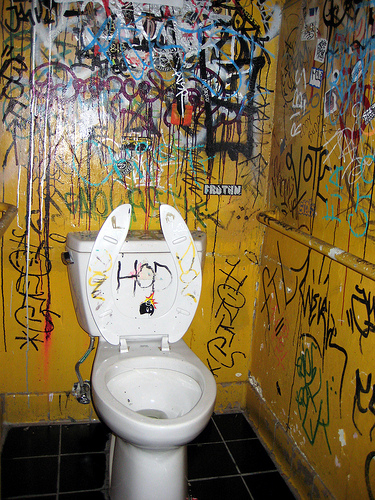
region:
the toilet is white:
[34, 180, 290, 498]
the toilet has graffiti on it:
[57, 199, 243, 487]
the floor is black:
[0, 379, 304, 499]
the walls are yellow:
[1, 1, 374, 498]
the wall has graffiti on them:
[9, 6, 373, 295]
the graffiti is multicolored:
[7, 7, 368, 266]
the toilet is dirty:
[39, 200, 218, 499]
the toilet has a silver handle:
[55, 236, 112, 285]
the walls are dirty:
[2, 212, 374, 498]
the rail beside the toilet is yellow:
[242, 194, 373, 297]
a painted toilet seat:
[81, 203, 205, 348]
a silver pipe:
[69, 333, 97, 407]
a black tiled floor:
[1, 406, 302, 499]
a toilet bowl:
[87, 354, 218, 450]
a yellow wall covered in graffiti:
[0, 0, 248, 424]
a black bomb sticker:
[137, 289, 161, 320]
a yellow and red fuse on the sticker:
[139, 289, 160, 310]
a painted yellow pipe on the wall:
[253, 206, 374, 286]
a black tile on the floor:
[57, 450, 112, 493]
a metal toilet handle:
[56, 248, 76, 267]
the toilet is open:
[61, 193, 254, 495]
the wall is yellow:
[256, 179, 350, 442]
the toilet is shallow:
[85, 349, 230, 454]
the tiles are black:
[25, 441, 91, 483]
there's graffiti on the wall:
[64, 2, 226, 190]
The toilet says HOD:
[110, 254, 182, 299]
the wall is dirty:
[50, 25, 235, 162]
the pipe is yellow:
[253, 203, 371, 269]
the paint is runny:
[21, 11, 56, 298]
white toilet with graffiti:
[77, 170, 218, 491]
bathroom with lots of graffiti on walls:
[36, 2, 367, 488]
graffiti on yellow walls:
[142, 13, 322, 166]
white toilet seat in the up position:
[90, 191, 204, 354]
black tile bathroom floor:
[18, 425, 101, 491]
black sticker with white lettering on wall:
[194, 175, 259, 203]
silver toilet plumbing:
[63, 328, 105, 409]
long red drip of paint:
[331, 228, 359, 324]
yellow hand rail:
[253, 216, 349, 266]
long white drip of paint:
[20, 134, 44, 395]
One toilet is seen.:
[68, 222, 213, 439]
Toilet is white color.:
[75, 248, 198, 461]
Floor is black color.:
[28, 443, 88, 488]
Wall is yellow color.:
[248, 313, 354, 406]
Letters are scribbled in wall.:
[33, 39, 262, 148]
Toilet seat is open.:
[71, 276, 234, 451]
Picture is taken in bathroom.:
[30, 27, 276, 480]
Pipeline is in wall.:
[251, 210, 372, 271]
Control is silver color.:
[71, 375, 95, 407]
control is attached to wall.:
[68, 377, 98, 409]